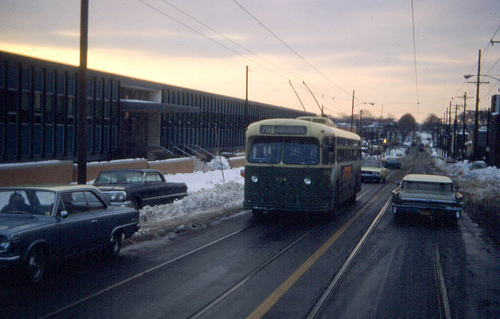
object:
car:
[2, 184, 139, 284]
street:
[1, 131, 500, 318]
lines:
[141, 2, 292, 88]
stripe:
[236, 166, 401, 318]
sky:
[1, 3, 498, 125]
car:
[92, 167, 190, 210]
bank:
[451, 161, 499, 187]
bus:
[242, 116, 364, 215]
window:
[284, 140, 318, 166]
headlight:
[304, 177, 312, 187]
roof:
[403, 174, 452, 185]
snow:
[430, 141, 500, 240]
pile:
[463, 166, 496, 203]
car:
[360, 160, 391, 183]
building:
[2, 46, 317, 187]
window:
[53, 70, 68, 96]